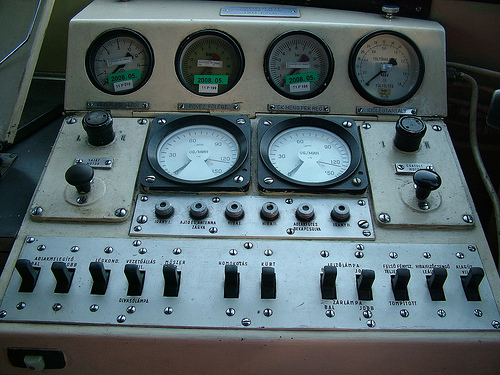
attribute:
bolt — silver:
[91, 306, 96, 313]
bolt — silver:
[117, 315, 124, 323]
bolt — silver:
[226, 311, 232, 318]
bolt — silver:
[326, 312, 332, 318]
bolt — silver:
[401, 311, 407, 317]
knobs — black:
[393, 115, 423, 147]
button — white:
[10, 337, 67, 373]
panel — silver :
[4, 240, 494, 322]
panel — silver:
[220, 0, 303, 20]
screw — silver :
[241, 317, 252, 326]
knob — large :
[387, 102, 447, 156]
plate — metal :
[220, 7, 300, 17]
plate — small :
[210, 6, 313, 27]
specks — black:
[215, 335, 295, 349]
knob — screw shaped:
[56, 157, 113, 202]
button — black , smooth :
[413, 168, 443, 213]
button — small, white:
[17, 354, 64, 371]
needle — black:
[360, 67, 386, 90]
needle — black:
[284, 52, 306, 86]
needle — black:
[105, 57, 125, 84]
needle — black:
[192, 51, 219, 86]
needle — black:
[287, 146, 312, 174]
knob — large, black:
[80, 108, 115, 147]